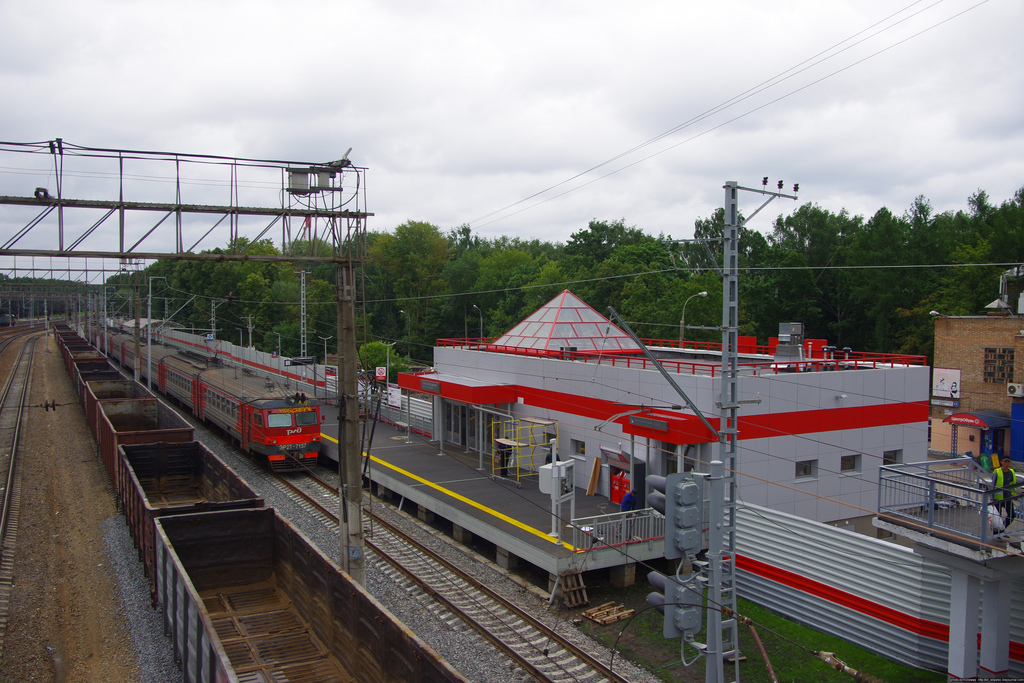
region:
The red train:
[93, 316, 328, 484]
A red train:
[93, 307, 350, 491]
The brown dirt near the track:
[11, 323, 166, 679]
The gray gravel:
[85, 496, 187, 680]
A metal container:
[129, 496, 480, 675]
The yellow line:
[315, 424, 573, 567]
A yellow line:
[324, 431, 582, 569]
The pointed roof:
[485, 279, 634, 375]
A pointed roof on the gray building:
[507, 283, 625, 354]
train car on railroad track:
[144, 501, 462, 676]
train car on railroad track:
[108, 431, 263, 562]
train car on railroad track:
[87, 384, 195, 462]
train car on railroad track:
[77, 365, 155, 420]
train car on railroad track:
[76, 359, 125, 383]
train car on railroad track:
[153, 340, 223, 418]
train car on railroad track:
[130, 337, 166, 389]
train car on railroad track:
[194, 346, 324, 477]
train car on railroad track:
[57, 327, 99, 359]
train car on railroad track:
[134, 334, 177, 393]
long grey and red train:
[73, 312, 327, 478]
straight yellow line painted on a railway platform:
[325, 426, 582, 563]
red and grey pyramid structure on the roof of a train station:
[486, 285, 649, 361]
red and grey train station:
[394, 288, 932, 527]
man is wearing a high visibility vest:
[982, 452, 1022, 539]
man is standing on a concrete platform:
[868, 445, 1023, 566]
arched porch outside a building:
[938, 405, 1008, 464]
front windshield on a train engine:
[266, 407, 293, 428]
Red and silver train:
[80, 316, 324, 476]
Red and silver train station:
[364, 282, 935, 606]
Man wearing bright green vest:
[984, 451, 1019, 543]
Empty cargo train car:
[150, 503, 471, 680]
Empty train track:
[0, 328, 49, 655]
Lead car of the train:
[196, 363, 324, 477]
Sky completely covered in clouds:
[1, 2, 1022, 268]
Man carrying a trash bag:
[977, 451, 1015, 544]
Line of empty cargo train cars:
[48, 320, 464, 679]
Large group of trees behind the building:
[108, 183, 1022, 365]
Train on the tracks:
[61, 304, 331, 479]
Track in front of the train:
[288, 456, 618, 679]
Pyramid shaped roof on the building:
[484, 282, 653, 360]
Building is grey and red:
[375, 277, 1021, 679]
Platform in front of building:
[289, 395, 675, 579]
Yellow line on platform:
[314, 418, 583, 562]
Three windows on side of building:
[789, 437, 913, 486]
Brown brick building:
[918, 298, 1021, 467]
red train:
[99, 306, 338, 500]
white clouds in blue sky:
[393, 61, 466, 109]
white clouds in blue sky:
[554, 69, 663, 155]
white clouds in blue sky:
[887, 107, 960, 178]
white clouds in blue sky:
[440, 153, 510, 205]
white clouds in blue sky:
[339, 20, 431, 65]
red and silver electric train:
[94, 313, 330, 469]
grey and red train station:
[393, 280, 918, 524]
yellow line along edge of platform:
[319, 428, 570, 558]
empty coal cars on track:
[47, 307, 450, 677]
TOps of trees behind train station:
[101, 178, 1016, 341]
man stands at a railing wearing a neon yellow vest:
[989, 445, 1022, 528]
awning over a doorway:
[935, 402, 1012, 435]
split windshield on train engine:
[269, 401, 318, 433]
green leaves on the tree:
[611, 238, 643, 267]